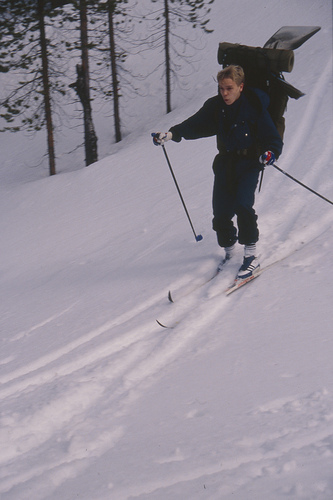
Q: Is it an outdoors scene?
A: Yes, it is outdoors.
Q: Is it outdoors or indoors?
A: It is outdoors.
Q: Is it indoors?
A: No, it is outdoors.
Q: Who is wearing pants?
A: The skier is wearing pants.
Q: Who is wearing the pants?
A: The skier is wearing pants.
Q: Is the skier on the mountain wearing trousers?
A: Yes, the skier is wearing trousers.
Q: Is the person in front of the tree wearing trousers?
A: Yes, the skier is wearing trousers.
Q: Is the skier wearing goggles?
A: No, the skier is wearing trousers.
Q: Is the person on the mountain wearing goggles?
A: No, the skier is wearing trousers.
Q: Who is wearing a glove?
A: The skier is wearing a glove.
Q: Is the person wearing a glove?
A: Yes, the skier is wearing a glove.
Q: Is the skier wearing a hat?
A: No, the skier is wearing a glove.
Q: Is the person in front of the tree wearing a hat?
A: No, the skier is wearing a glove.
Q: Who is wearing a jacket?
A: The skier is wearing a jacket.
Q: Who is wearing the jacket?
A: The skier is wearing a jacket.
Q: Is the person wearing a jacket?
A: Yes, the skier is wearing a jacket.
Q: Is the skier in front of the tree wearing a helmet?
A: No, the skier is wearing a jacket.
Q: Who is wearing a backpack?
A: The skier is wearing a backpack.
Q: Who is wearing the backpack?
A: The skier is wearing a backpack.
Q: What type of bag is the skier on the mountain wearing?
A: The skier is wearing a backpack.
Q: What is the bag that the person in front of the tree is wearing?
A: The bag is a backpack.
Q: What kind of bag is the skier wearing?
A: The skier is wearing a backpack.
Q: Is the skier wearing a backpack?
A: Yes, the skier is wearing a backpack.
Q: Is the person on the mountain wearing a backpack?
A: Yes, the skier is wearing a backpack.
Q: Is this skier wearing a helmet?
A: No, the skier is wearing a backpack.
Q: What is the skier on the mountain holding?
A: The skier is holding the pole.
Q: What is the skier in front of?
A: The skier is in front of the tree.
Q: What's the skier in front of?
A: The skier is in front of the tree.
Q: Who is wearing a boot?
A: The skier is wearing a boot.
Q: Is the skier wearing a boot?
A: Yes, the skier is wearing a boot.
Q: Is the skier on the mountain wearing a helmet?
A: No, the skier is wearing a boot.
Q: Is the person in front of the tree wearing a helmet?
A: No, the skier is wearing a boot.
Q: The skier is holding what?
A: The skier is holding the pole.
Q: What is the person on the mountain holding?
A: The skier is holding the pole.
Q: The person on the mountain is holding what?
A: The skier is holding the pole.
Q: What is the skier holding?
A: The skier is holding the pole.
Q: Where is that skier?
A: The skier is on the mountain.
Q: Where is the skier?
A: The skier is on the mountain.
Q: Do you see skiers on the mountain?
A: Yes, there is a skier on the mountain.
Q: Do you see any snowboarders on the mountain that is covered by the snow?
A: No, there is a skier on the mountain.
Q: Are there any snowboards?
A: No, there are no snowboards.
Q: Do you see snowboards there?
A: No, there are no snowboards.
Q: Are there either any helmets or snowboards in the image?
A: No, there are no snowboards or helmets.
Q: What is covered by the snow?
A: The mountain is covered by the snow.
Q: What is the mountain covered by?
A: The mountain is covered by the snow.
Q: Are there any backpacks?
A: Yes, there is a backpack.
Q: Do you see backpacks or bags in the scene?
A: Yes, there is a backpack.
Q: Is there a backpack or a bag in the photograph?
A: Yes, there is a backpack.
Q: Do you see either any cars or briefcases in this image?
A: No, there are no cars or briefcases.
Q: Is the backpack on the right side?
A: Yes, the backpack is on the right of the image.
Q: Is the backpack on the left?
A: No, the backpack is on the right of the image.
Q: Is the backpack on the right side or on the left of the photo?
A: The backpack is on the right of the image.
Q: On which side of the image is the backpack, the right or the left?
A: The backpack is on the right of the image.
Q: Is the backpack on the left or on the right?
A: The backpack is on the right of the image.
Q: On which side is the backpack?
A: The backpack is on the right of the image.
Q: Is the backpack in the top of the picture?
A: Yes, the backpack is in the top of the image.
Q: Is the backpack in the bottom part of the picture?
A: No, the backpack is in the top of the image.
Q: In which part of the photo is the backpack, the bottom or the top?
A: The backpack is in the top of the image.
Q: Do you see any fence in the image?
A: No, there are no fences.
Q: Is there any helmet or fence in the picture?
A: No, there are no fences or helmets.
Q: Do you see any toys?
A: No, there are no toys.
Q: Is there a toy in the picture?
A: No, there are no toys.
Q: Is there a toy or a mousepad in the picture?
A: No, there are no toys or mouse pads.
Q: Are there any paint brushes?
A: No, there are no paint brushes.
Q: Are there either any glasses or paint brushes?
A: No, there are no paint brushes or glasses.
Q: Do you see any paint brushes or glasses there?
A: No, there are no paint brushes or glasses.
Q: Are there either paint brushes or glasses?
A: No, there are no paint brushes or glasses.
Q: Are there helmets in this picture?
A: No, there are no helmets.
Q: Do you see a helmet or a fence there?
A: No, there are no helmets or fences.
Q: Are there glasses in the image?
A: No, there are no glasses.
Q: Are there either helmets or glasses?
A: No, there are no glasses or helmets.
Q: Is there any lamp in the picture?
A: No, there are no lamps.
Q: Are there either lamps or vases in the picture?
A: No, there are no lamps or vases.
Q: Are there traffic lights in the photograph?
A: No, there are no traffic lights.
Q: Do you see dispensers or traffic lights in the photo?
A: No, there are no traffic lights or dispensers.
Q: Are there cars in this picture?
A: No, there are no cars.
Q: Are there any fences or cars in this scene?
A: No, there are no cars or fences.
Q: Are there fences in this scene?
A: No, there are no fences.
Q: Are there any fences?
A: No, there are no fences.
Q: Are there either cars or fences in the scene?
A: No, there are no fences or cars.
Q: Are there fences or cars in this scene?
A: No, there are no fences or cars.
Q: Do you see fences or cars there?
A: No, there are no fences or cars.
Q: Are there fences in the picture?
A: No, there are no fences.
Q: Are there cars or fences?
A: No, there are no fences or cars.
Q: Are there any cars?
A: No, there are no cars.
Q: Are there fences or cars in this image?
A: No, there are no cars or fences.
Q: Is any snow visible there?
A: Yes, there is snow.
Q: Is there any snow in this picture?
A: Yes, there is snow.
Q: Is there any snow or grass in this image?
A: Yes, there is snow.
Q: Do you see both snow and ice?
A: No, there is snow but no ice.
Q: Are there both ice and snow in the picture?
A: No, there is snow but no ice.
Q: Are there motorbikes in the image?
A: No, there are no motorbikes.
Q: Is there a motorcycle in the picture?
A: No, there are no motorcycles.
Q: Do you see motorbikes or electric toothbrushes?
A: No, there are no motorbikes or electric toothbrushes.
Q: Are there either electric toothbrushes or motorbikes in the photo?
A: No, there are no motorbikes or electric toothbrushes.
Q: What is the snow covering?
A: The snow is covering the mountain.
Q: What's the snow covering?
A: The snow is covering the mountain.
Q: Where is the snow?
A: The snow is on the mountain.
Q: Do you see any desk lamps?
A: No, there are no desk lamps.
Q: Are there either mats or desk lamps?
A: No, there are no desk lamps or mats.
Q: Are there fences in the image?
A: No, there are no fences.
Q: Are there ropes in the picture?
A: No, there are no ropes.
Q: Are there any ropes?
A: No, there are no ropes.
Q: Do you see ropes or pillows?
A: No, there are no ropes or pillows.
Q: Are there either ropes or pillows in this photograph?
A: No, there are no ropes or pillows.